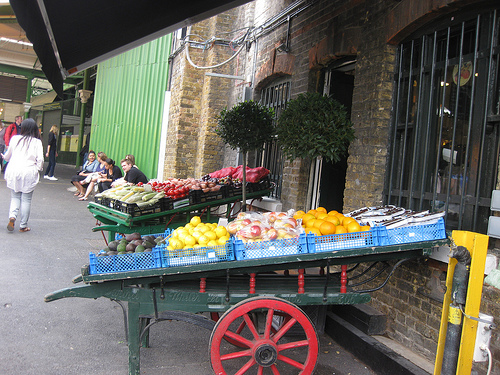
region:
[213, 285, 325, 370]
red wheel on the ground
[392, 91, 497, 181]
black bars on window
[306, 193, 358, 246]
oranges on fruit cart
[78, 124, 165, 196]
people sitting near each other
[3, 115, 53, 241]
girl walking down the street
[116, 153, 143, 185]
man looking to his left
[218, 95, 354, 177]
two small trees next to fruit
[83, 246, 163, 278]
blue basket holding fruit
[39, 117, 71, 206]
lady with white shoes on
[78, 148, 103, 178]
two women talking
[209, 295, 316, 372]
red wooden wheel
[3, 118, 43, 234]
woman in white walking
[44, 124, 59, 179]
woman standing in black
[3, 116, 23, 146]
man in red coat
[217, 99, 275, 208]
tree next to the doorway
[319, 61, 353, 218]
open doorway of brick building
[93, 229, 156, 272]
blue basket with avocados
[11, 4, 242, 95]
section of overhang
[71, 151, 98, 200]
woman in blue shirt sitting on bench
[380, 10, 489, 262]
metal bars over window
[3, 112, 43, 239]
A woman wearig a white shirt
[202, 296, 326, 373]
The red wheel of the cart.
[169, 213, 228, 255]
A pile of lemons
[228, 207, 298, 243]
A pile of apples.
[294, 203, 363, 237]
A pile of oranges.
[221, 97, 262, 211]
A small tree.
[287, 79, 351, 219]
A small green tree.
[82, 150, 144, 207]
A group of people sitting on a bench.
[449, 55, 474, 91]
A sign advertising fruit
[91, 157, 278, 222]
A cart of fruit and vegetables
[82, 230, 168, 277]
Blue crate of avocados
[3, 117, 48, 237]
Woman wearing white top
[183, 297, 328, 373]
Red wheel on cart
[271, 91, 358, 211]
Plant sitting near doorway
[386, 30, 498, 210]
Black bars on window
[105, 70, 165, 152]
Green siding on wall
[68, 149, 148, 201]
Group of people sitting near green wall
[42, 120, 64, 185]
Woman wearing white shoes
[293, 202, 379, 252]
Blue crate of oranges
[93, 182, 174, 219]
Black crate of corn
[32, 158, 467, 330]
fruit and vegetable cars on sidewalk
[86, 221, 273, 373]
avocados and lemons on the cart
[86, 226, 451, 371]
red wheel on the cart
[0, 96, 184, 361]
lady walked past the fruit and vegetables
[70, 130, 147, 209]
people sitting on bench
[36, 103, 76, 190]
lady looking in the window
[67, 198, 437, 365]
cart contains avocados, lemons, apples, oranges and cherries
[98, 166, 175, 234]
corn on display outside store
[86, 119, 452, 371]
food on display outside store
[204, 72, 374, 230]
two plants at the entrance to the store